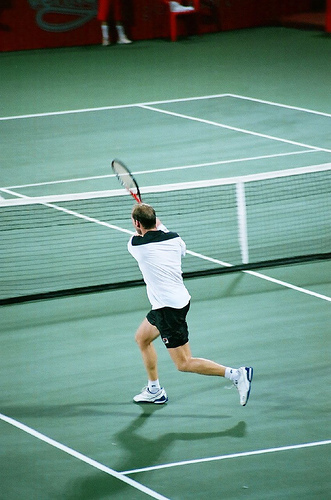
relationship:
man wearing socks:
[127, 203, 253, 407] [223, 360, 241, 381]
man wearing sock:
[127, 203, 253, 407] [223, 365, 241, 381]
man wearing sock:
[127, 203, 253, 407] [144, 378, 161, 393]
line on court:
[248, 264, 310, 294] [3, 25, 325, 499]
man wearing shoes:
[80, 185, 266, 434] [111, 349, 284, 426]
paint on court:
[1, 402, 326, 497] [3, 25, 325, 499]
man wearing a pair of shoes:
[127, 203, 253, 407] [133, 365, 254, 408]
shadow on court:
[67, 400, 248, 499] [3, 25, 325, 499]